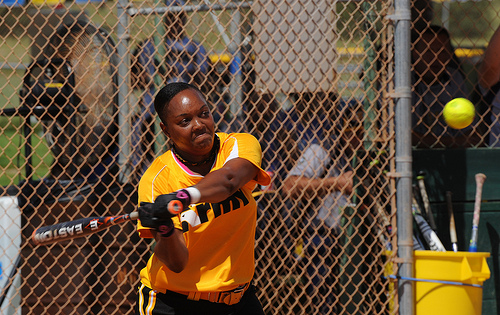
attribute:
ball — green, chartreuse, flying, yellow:
[443, 97, 476, 132]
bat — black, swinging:
[32, 210, 136, 245]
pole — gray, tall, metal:
[393, 0, 415, 314]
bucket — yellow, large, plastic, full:
[383, 250, 492, 314]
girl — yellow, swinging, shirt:
[138, 82, 261, 314]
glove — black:
[155, 191, 190, 219]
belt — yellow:
[186, 291, 247, 306]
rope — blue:
[387, 273, 485, 290]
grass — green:
[1, 119, 51, 191]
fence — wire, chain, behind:
[321, 31, 368, 75]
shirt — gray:
[286, 135, 350, 226]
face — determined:
[177, 107, 215, 148]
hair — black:
[153, 83, 197, 111]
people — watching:
[135, 12, 211, 96]